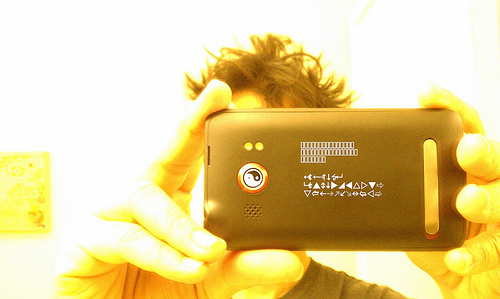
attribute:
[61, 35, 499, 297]
man — light skinned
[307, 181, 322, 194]
symbol — white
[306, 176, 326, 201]
symbol — white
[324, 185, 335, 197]
symbol — white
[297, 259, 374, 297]
shirt — black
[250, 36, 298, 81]
hair — long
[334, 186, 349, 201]
symbol — white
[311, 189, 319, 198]
symbol — white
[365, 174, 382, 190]
symbol — white